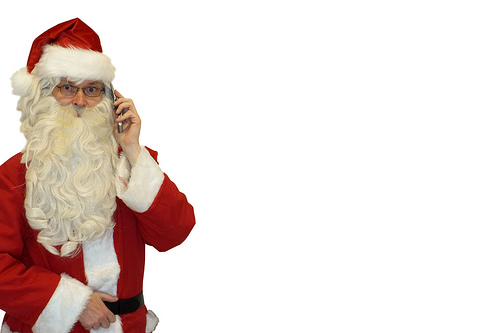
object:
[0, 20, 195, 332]
santa outfit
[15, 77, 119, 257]
beard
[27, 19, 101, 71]
red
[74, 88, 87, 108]
nose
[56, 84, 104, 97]
glasses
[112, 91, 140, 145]
left hand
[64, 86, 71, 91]
eye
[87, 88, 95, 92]
eye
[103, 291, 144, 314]
belt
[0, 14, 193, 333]
clothes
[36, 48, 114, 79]
trim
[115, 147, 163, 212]
trim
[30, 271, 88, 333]
trim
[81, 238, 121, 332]
trim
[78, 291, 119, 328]
hand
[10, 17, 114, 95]
hat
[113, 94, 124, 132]
cell phone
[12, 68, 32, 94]
ball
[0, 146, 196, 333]
jacket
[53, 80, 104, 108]
face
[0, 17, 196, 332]
santa